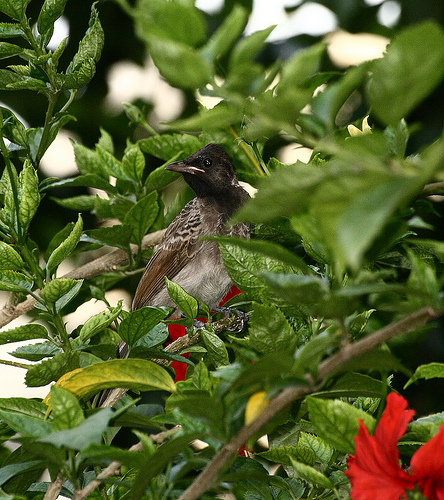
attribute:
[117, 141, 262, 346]
bird — sitting, small, alert, feathered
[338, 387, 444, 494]
flower — bright, in bloom, red, brilliant red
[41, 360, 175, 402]
leaf — yellowing, deep green, turning yellow, orange in color, orange colored, orange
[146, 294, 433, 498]
branch — small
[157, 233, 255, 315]
belly — white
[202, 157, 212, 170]
eye — black, beady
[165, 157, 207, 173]
beak — grey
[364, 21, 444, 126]
leaf — luxuriant, green, healthy